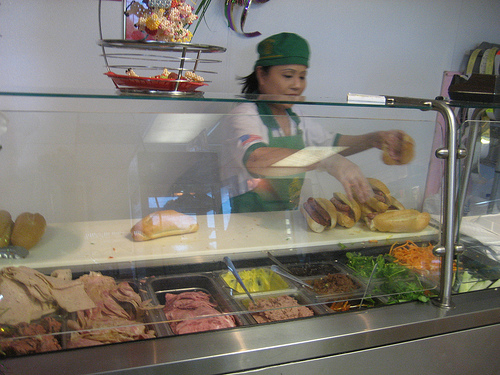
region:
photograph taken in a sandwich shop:
[7, 10, 486, 370]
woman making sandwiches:
[217, 33, 357, 241]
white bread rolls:
[2, 198, 204, 252]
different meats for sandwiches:
[7, 253, 213, 357]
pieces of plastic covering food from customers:
[5, 120, 496, 337]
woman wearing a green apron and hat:
[220, 37, 342, 214]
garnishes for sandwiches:
[242, 232, 469, 321]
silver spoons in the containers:
[217, 248, 312, 314]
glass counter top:
[5, 55, 487, 120]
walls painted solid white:
[35, 0, 391, 196]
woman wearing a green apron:
[226, 33, 318, 210]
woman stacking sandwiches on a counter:
[227, 32, 422, 234]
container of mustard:
[224, 264, 286, 292]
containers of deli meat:
[0, 264, 234, 347]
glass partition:
[0, 104, 447, 340]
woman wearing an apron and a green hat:
[218, 32, 400, 228]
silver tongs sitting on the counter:
[0, 246, 34, 260]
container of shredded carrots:
[392, 242, 450, 271]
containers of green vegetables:
[356, 250, 420, 308]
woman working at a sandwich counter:
[214, 27, 355, 247]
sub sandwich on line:
[300, 190, 342, 235]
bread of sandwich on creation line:
[124, 208, 201, 233]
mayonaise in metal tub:
[225, 265, 290, 293]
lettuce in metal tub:
[339, 250, 426, 307]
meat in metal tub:
[158, 283, 230, 335]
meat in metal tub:
[0, 263, 64, 314]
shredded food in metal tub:
[395, 236, 444, 273]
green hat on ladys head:
[253, 31, 314, 70]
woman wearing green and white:
[221, 93, 340, 210]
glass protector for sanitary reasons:
[1, 100, 454, 331]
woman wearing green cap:
[241, 27, 312, 107]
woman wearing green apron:
[222, 28, 330, 213]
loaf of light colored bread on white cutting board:
[123, 204, 201, 244]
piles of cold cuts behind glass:
[2, 266, 238, 348]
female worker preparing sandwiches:
[222, 30, 433, 244]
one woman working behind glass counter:
[3, 28, 490, 321]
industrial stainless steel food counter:
[2, 232, 497, 374]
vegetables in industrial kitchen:
[351, 235, 499, 307]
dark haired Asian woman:
[234, 28, 317, 110]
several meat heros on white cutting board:
[297, 175, 429, 240]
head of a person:
[243, 25, 320, 115]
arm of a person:
[325, 125, 395, 165]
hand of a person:
[363, 128, 414, 155]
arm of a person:
[269, 140, 340, 190]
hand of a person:
[315, 160, 385, 205]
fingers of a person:
[337, 172, 379, 225]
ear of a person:
[251, 54, 270, 83]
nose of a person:
[286, 79, 303, 91]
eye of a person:
[280, 68, 294, 82]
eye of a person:
[296, 71, 308, 83]